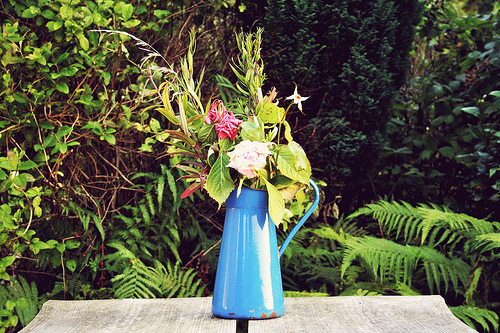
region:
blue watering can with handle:
[211, 183, 318, 313]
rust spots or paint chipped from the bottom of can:
[211, 306, 288, 319]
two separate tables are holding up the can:
[43, 295, 460, 332]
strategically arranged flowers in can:
[164, 40, 308, 212]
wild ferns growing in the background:
[338, 188, 499, 293]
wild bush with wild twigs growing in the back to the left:
[8, 14, 181, 242]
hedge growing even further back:
[296, 1, 369, 169]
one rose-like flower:
[228, 137, 273, 181]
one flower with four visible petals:
[285, 79, 312, 116]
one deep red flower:
[210, 102, 240, 137]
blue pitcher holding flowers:
[84, 13, 370, 323]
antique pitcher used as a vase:
[124, 26, 334, 326]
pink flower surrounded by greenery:
[216, 135, 280, 182]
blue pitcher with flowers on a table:
[23, 36, 483, 331]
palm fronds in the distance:
[320, 198, 499, 293]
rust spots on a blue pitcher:
[223, 303, 290, 327]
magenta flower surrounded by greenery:
[195, 94, 242, 141]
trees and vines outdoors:
[0, 22, 140, 293]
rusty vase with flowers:
[122, 33, 334, 330]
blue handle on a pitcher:
[277, 171, 332, 253]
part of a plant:
[230, 50, 265, 92]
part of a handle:
[301, 190, 319, 209]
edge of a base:
[238, 303, 267, 325]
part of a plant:
[354, 222, 406, 288]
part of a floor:
[361, 295, 386, 319]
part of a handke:
[291, 226, 317, 284]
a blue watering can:
[206, 165, 317, 318]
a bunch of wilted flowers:
[165, 25, 310, 195]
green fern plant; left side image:
[335, 200, 495, 285]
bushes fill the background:
[285, 15, 495, 200]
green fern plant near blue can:
[105, 255, 205, 295]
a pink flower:
[206, 91, 236, 142]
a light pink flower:
[229, 137, 274, 177]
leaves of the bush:
[51, 78, 71, 93]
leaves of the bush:
[457, 103, 478, 118]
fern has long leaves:
[422, 258, 434, 287]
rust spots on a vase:
[214, 298, 294, 325]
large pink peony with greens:
[221, 137, 281, 179]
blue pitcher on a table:
[113, 22, 373, 328]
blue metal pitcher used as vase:
[114, 25, 341, 327]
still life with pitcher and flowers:
[111, 30, 347, 332]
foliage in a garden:
[331, 17, 498, 289]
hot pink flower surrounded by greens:
[206, 97, 241, 142]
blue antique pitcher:
[196, 172, 325, 331]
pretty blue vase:
[121, 30, 341, 330]